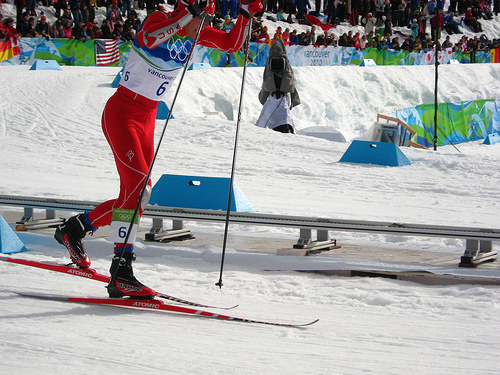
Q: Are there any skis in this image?
A: Yes, there are skis.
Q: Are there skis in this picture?
A: Yes, there are skis.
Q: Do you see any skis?
A: Yes, there are skis.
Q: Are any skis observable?
A: Yes, there are skis.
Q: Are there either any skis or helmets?
A: Yes, there are skis.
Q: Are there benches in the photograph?
A: No, there are no benches.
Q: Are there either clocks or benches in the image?
A: No, there are no benches or clocks.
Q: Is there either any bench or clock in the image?
A: No, there are no benches or clocks.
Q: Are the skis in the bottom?
A: Yes, the skis are in the bottom of the image.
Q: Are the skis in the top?
A: No, the skis are in the bottom of the image.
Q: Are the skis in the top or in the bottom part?
A: The skis are in the bottom of the image.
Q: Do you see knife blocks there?
A: No, there are no knife blocks.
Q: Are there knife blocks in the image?
A: No, there are no knife blocks.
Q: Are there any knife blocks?
A: No, there are no knife blocks.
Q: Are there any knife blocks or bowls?
A: No, there are no knife blocks or bowls.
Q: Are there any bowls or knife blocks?
A: No, there are no knife blocks or bowls.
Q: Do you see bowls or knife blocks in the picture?
A: No, there are no knife blocks or bowls.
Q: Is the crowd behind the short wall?
A: Yes, the crowd is behind the wall.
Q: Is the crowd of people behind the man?
A: Yes, the crowd is behind the man.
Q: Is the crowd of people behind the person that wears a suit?
A: Yes, the crowd is behind the man.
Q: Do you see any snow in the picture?
A: Yes, there is snow.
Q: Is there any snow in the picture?
A: Yes, there is snow.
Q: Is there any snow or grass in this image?
A: Yes, there is snow.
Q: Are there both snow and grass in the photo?
A: No, there is snow but no grass.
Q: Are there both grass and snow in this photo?
A: No, there is snow but no grass.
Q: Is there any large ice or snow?
A: Yes, there is large snow.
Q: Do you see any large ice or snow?
A: Yes, there is large snow.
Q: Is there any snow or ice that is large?
A: Yes, the snow is large.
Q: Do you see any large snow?
A: Yes, there is large snow.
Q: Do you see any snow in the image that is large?
A: Yes, there is snow that is large.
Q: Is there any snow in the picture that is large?
A: Yes, there is snow that is large.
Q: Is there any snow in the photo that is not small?
A: Yes, there is large snow.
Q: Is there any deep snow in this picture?
A: Yes, there is deep snow.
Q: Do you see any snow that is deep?
A: Yes, there is deep snow.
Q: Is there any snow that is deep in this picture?
A: Yes, there is deep snow.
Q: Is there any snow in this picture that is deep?
A: Yes, there is snow that is deep.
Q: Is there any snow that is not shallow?
A: Yes, there is deep snow.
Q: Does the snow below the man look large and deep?
A: Yes, the snow is large and deep.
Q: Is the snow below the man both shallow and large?
A: No, the snow is large but deep.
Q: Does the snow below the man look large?
A: Yes, the snow is large.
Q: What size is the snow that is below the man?
A: The snow is large.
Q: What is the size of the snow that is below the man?
A: The snow is large.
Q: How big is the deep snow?
A: The snow is large.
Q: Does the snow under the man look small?
A: No, the snow is large.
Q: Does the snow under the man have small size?
A: No, the snow is large.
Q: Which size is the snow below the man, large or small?
A: The snow is large.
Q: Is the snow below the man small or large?
A: The snow is large.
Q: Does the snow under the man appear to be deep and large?
A: Yes, the snow is deep and large.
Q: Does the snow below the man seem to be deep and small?
A: No, the snow is deep but large.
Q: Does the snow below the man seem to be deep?
A: Yes, the snow is deep.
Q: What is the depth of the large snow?
A: The snow is deep.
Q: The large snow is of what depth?
A: The snow is deep.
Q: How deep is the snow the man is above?
A: The snow is deep.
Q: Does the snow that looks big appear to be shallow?
A: No, the snow is deep.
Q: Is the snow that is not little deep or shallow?
A: The snow is deep.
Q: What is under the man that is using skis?
A: The snow is under the man.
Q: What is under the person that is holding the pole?
A: The snow is under the man.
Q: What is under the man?
A: The snow is under the man.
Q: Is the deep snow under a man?
A: Yes, the snow is under a man.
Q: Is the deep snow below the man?
A: Yes, the snow is below the man.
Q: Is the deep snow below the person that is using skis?
A: Yes, the snow is below the man.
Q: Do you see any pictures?
A: No, there are no pictures.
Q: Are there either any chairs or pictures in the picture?
A: No, there are no pictures or chairs.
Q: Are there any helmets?
A: Yes, there is a helmet.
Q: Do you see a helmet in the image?
A: Yes, there is a helmet.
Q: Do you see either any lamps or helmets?
A: Yes, there is a helmet.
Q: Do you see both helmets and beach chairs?
A: No, there is a helmet but no beach chairs.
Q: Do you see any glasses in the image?
A: No, there are no glasses.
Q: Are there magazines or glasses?
A: No, there are no glasses or magazines.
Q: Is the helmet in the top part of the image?
A: Yes, the helmet is in the top of the image.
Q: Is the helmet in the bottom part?
A: No, the helmet is in the top of the image.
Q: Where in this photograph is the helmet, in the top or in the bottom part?
A: The helmet is in the top of the image.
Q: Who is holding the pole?
A: The man is holding the pole.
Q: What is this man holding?
A: The man is holding the pole.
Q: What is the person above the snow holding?
A: The man is holding the pole.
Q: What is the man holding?
A: The man is holding the pole.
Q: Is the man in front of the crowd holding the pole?
A: Yes, the man is holding the pole.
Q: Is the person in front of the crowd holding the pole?
A: Yes, the man is holding the pole.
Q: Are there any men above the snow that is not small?
A: Yes, there is a man above the snow.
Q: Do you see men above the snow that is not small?
A: Yes, there is a man above the snow.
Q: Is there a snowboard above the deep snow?
A: No, there is a man above the snow.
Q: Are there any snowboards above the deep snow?
A: No, there is a man above the snow.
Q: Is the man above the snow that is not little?
A: Yes, the man is above the snow.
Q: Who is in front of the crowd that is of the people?
A: The man is in front of the crowd.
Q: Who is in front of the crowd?
A: The man is in front of the crowd.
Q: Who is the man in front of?
A: The man is in front of the crowd.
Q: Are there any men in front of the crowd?
A: Yes, there is a man in front of the crowd.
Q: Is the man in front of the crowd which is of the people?
A: Yes, the man is in front of the crowd.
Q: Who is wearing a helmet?
A: The man is wearing a helmet.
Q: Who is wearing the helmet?
A: The man is wearing a helmet.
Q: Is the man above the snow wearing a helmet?
A: Yes, the man is wearing a helmet.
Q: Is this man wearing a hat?
A: No, the man is wearing a helmet.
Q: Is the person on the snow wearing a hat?
A: No, the man is wearing a helmet.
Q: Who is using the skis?
A: The man is using the skis.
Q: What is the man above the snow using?
A: The man is using skis.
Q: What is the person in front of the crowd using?
A: The man is using skis.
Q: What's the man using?
A: The man is using skis.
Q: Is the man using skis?
A: Yes, the man is using skis.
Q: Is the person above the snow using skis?
A: Yes, the man is using skis.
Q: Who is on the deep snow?
A: The man is on the snow.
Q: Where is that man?
A: The man is on the snow.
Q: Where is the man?
A: The man is on the snow.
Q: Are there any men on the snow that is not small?
A: Yes, there is a man on the snow.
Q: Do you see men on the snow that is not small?
A: Yes, there is a man on the snow.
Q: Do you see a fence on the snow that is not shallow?
A: No, there is a man on the snow.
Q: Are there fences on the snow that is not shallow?
A: No, there is a man on the snow.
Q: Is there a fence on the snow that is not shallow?
A: No, there is a man on the snow.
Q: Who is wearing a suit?
A: The man is wearing a suit.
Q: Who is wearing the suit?
A: The man is wearing a suit.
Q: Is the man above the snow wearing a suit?
A: Yes, the man is wearing a suit.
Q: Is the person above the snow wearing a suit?
A: Yes, the man is wearing a suit.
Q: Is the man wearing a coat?
A: No, the man is wearing a suit.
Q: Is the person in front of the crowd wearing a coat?
A: No, the man is wearing a suit.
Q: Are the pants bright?
A: Yes, the pants are bright.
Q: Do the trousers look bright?
A: Yes, the trousers are bright.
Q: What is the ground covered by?
A: The ground is covered by the snow.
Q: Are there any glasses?
A: No, there are no glasses.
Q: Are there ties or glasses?
A: No, there are no glasses or ties.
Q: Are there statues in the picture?
A: No, there are no statues.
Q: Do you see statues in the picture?
A: No, there are no statues.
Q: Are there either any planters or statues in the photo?
A: No, there are no statues or planters.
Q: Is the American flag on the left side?
A: Yes, the American flag is on the left of the image.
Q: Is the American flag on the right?
A: No, the American flag is on the left of the image.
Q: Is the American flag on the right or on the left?
A: The American flag is on the left of the image.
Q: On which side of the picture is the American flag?
A: The American flag is on the left of the image.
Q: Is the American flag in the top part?
A: Yes, the American flag is in the top of the image.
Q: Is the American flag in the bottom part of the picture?
A: No, the American flag is in the top of the image.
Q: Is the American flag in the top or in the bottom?
A: The American flag is in the top of the image.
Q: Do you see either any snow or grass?
A: Yes, there is snow.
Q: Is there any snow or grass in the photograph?
A: Yes, there is snow.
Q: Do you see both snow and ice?
A: No, there is snow but no ice.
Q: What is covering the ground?
A: The snow is covering the ground.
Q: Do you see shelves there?
A: No, there are no shelves.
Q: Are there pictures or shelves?
A: No, there are no shelves or pictures.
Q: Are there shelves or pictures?
A: No, there are no shelves or pictures.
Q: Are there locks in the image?
A: No, there are no locks.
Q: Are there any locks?
A: No, there are no locks.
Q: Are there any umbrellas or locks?
A: No, there are no locks or umbrellas.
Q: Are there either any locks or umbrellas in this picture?
A: No, there are no locks or umbrellas.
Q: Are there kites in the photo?
A: No, there are no kites.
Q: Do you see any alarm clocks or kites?
A: No, there are no kites or alarm clocks.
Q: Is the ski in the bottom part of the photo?
A: Yes, the ski is in the bottom of the image.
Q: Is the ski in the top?
A: No, the ski is in the bottom of the image.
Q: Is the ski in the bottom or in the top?
A: The ski is in the bottom of the image.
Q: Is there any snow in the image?
A: Yes, there is snow.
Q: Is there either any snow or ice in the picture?
A: Yes, there is snow.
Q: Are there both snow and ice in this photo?
A: No, there is snow but no ice.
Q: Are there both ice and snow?
A: No, there is snow but no ice.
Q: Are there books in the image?
A: No, there are no books.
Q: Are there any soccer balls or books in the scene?
A: No, there are no books or soccer balls.